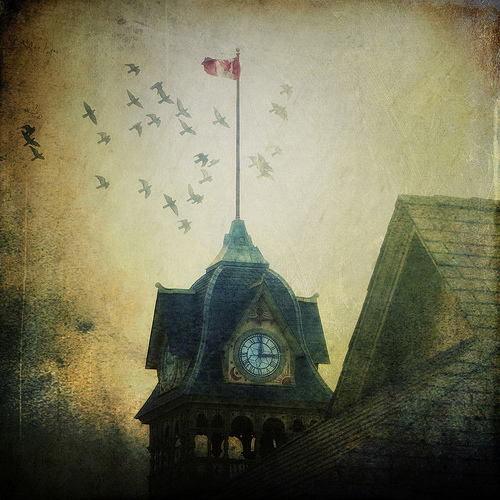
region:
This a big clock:
[228, 316, 301, 386]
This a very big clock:
[225, 323, 291, 386]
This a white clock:
[227, 318, 295, 388]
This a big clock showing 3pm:
[227, 316, 293, 386]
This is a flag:
[197, 29, 283, 241]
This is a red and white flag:
[199, 35, 264, 242]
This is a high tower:
[136, 44, 332, 499]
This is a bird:
[77, 93, 102, 127]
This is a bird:
[89, 125, 119, 152]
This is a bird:
[89, 167, 117, 197]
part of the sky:
[308, 97, 360, 166]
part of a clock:
[241, 327, 283, 377]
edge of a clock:
[267, 325, 282, 360]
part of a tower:
[215, 383, 257, 417]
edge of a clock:
[231, 347, 248, 371]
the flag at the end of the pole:
[202, 52, 244, 80]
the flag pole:
[231, 70, 248, 217]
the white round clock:
[239, 331, 281, 378]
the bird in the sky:
[73, 95, 103, 127]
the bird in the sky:
[213, 102, 230, 132]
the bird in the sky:
[177, 219, 194, 239]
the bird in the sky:
[133, 175, 153, 200]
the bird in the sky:
[27, 141, 44, 163]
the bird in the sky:
[271, 75, 296, 100]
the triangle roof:
[320, 181, 488, 363]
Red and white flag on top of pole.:
[204, 43, 307, 133]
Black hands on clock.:
[247, 337, 295, 376]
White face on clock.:
[242, 345, 298, 405]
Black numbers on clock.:
[240, 328, 302, 420]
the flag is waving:
[150, 1, 332, 91]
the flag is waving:
[183, 41, 390, 138]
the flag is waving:
[195, 38, 300, 119]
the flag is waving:
[190, 21, 342, 181]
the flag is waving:
[193, 2, 378, 293]